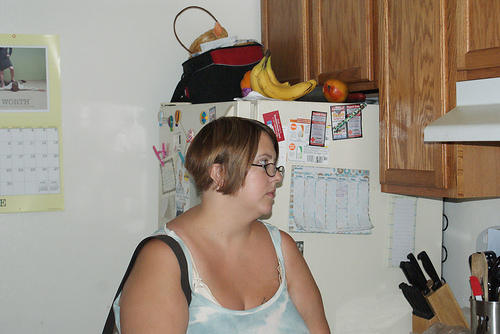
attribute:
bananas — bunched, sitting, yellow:
[241, 53, 313, 107]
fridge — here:
[163, 85, 405, 216]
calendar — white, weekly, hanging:
[299, 156, 391, 237]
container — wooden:
[418, 284, 460, 333]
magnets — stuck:
[159, 114, 201, 155]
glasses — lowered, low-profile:
[239, 166, 305, 189]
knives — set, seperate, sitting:
[388, 227, 432, 313]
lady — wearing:
[125, 109, 340, 334]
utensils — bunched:
[402, 257, 483, 331]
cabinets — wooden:
[266, 5, 441, 122]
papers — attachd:
[162, 168, 187, 199]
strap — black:
[126, 221, 222, 329]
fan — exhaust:
[441, 91, 499, 144]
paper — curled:
[290, 205, 392, 249]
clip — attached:
[140, 133, 172, 167]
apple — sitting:
[299, 75, 371, 119]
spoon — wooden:
[468, 251, 497, 290]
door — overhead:
[379, 15, 445, 197]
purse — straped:
[104, 257, 128, 334]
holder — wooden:
[412, 271, 448, 323]